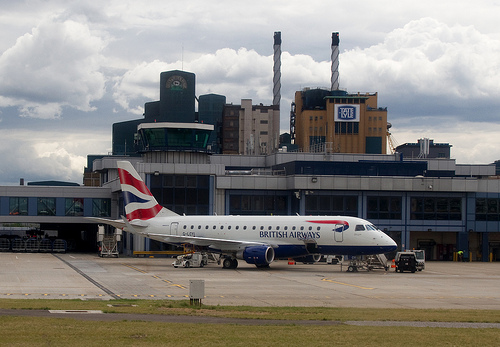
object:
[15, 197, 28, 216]
window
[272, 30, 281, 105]
smokestacks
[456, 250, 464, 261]
crewmember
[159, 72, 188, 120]
logo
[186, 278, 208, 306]
marking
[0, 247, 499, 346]
ground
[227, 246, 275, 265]
engine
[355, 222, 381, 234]
windshield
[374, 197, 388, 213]
window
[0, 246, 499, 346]
british airways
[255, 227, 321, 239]
logo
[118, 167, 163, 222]
design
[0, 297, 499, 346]
grass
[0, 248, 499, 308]
runway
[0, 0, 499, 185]
sky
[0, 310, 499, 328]
sidewalk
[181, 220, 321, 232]
window row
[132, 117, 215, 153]
watchtower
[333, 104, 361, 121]
logo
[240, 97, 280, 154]
building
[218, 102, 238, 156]
building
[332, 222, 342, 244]
door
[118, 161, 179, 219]
tail wing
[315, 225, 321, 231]
passenger windows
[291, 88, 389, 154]
industrial building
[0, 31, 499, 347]
airport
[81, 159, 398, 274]
airplane